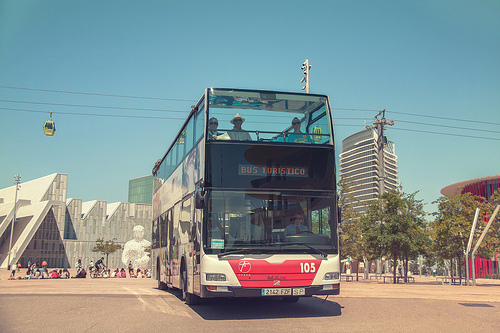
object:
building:
[339, 122, 400, 223]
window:
[205, 86, 337, 149]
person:
[204, 116, 224, 140]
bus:
[148, 85, 341, 307]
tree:
[429, 190, 484, 286]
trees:
[377, 182, 412, 285]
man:
[226, 113, 256, 142]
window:
[193, 93, 210, 148]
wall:
[36, 214, 63, 266]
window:
[203, 187, 337, 254]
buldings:
[0, 171, 161, 278]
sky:
[100, 39, 190, 84]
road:
[4, 275, 487, 329]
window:
[151, 188, 203, 248]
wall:
[22, 175, 60, 206]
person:
[287, 116, 313, 143]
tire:
[149, 253, 164, 290]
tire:
[177, 253, 189, 299]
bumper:
[197, 238, 344, 298]